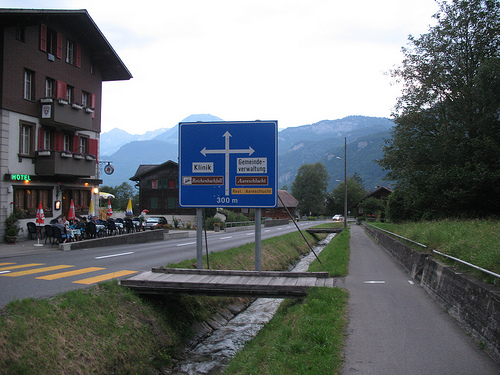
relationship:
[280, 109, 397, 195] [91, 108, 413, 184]
mountain on background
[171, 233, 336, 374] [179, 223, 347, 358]
waters on side road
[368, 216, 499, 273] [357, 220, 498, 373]
grass next wall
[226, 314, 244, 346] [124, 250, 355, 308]
waters below bridge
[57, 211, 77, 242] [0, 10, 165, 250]
people outside restaurant